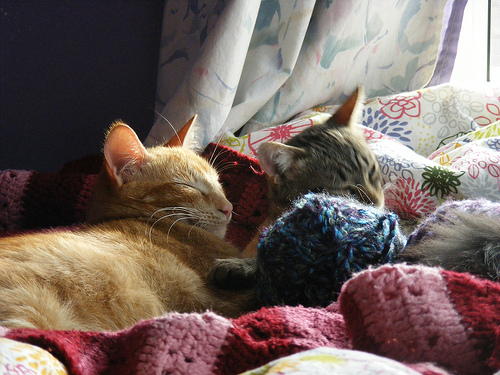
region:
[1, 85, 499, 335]
the two cats sleeping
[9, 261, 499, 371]
the crocheted yarn blanket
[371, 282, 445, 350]
the pink yarn on the blanket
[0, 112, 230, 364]
the light brown cat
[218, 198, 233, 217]
the nose on the cat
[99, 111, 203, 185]
the ears on the cat's head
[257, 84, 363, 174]
the ears on the cat's head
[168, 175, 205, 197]
the right eye on the cat's head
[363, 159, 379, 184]
the left eye on the cat's head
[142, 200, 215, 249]
the whiskers on the cat's face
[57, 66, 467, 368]
2 cats are sleeping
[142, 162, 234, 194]
the eyes are closed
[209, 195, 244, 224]
the nose is pink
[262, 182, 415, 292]
a ball of yarn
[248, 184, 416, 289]
the yarn is purple and blue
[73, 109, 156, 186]
the inside of the ear is pink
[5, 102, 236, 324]
the cat is gold colored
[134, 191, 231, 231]
the whiskers are white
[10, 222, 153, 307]
the sun is on the cats stomach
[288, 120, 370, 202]
the cat has black stripes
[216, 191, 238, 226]
Cat has pink nose.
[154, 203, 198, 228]
Cat has white whiskers.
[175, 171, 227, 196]
Cat's eyes are closed.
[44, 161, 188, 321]
Cat is laying on pink blanket.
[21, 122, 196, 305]
Cat has orange fur.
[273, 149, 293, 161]
White hair on inside of cat's ear.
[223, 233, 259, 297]
Cat has gray paw.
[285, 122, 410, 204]
Cat has gray head.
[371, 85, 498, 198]
Floral printed blanket near cats.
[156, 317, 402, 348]
Pink blanket is striped.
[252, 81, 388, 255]
grey and white kitten laying down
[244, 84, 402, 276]
grey and white kitten with eyes closed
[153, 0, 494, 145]
flowery curtain hanging at window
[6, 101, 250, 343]
orange and white cat laying down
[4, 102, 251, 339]
orange and white cat has eyes open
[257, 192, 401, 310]
ball of blue yarn laying on bed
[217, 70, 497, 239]
decorative cover on bed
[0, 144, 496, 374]
knitted blanket laying on bed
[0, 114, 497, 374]
orange and white cat laying on knitted blanket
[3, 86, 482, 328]
two animals laying together on a bed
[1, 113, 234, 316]
an orange tabby cat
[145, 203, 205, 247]
the orange tabby cats white whiskers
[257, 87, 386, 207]
a grey tiger cat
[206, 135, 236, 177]
a tabby's white eyebrows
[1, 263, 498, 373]
a purple and pink afghan blanket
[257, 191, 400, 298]
a blue knit blanket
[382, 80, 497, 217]
a white floral bed sheet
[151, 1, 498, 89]
a white sheet curtain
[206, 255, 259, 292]
the grey tiger cats paw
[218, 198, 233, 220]
the orange tabby's pink nose